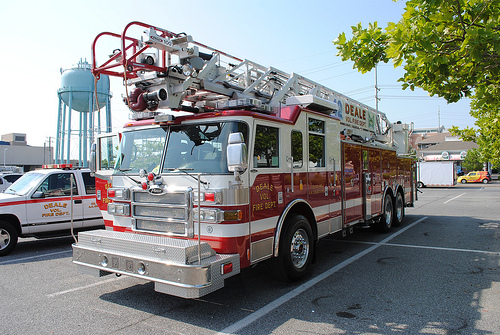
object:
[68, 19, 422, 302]
fire truck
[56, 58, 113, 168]
tower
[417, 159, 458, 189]
trailer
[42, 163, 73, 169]
siren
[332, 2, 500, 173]
tree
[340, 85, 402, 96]
power lines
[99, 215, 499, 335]
shadow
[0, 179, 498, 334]
ground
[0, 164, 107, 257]
vehicle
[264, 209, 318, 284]
tire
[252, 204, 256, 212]
lettering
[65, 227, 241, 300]
bumper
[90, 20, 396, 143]
ladder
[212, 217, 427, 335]
lines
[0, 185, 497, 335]
lot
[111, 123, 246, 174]
windshield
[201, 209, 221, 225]
lights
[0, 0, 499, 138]
sky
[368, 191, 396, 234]
rear tire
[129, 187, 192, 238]
grill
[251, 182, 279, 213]
name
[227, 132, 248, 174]
mirror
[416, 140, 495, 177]
building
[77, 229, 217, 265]
box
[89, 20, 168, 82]
rails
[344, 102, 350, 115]
writing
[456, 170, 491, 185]
car